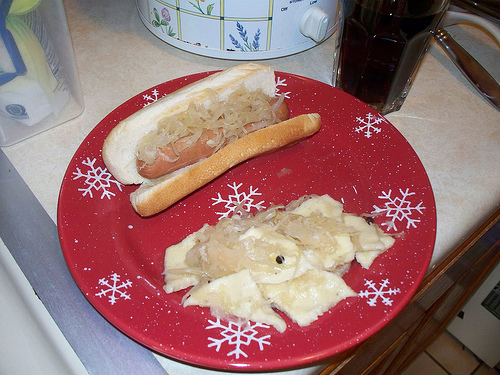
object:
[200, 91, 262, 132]
sauerkraut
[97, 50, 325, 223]
hot dog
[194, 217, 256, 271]
sauerkraut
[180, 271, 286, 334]
ravioli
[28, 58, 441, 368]
plate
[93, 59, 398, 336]
dinner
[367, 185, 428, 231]
snowflakes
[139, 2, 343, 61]
crock pot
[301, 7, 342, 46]
dial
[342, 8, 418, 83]
soda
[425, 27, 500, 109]
silverware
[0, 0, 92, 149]
canister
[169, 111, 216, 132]
cheese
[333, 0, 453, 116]
bottom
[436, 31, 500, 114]
knife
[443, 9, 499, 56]
handle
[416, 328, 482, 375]
floor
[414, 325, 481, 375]
tile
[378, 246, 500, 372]
doors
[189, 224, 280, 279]
pasta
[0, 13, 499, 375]
table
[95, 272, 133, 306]
snowflakes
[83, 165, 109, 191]
stars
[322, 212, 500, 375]
front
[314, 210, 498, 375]
cabinet